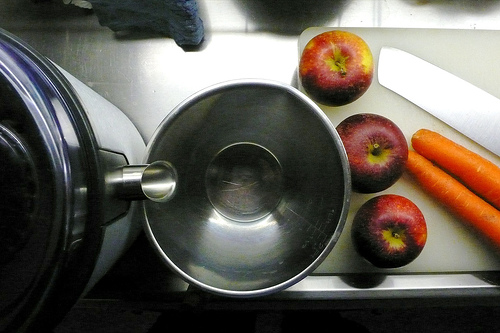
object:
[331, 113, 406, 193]
apple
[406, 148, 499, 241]
carrot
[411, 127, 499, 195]
carrot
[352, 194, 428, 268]
apple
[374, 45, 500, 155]
knife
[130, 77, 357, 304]
bowl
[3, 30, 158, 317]
juicer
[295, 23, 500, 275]
board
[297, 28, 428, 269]
group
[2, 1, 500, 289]
counter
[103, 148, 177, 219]
nozzle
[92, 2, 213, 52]
cloth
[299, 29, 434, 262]
three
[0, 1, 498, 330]
photo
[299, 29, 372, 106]
apple